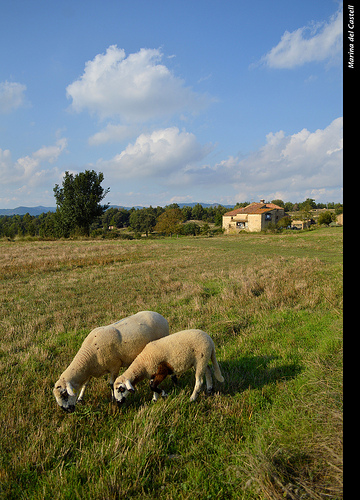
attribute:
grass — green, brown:
[1, 241, 342, 309]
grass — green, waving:
[227, 311, 335, 376]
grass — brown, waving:
[1, 244, 102, 269]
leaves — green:
[62, 179, 100, 223]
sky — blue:
[1, 0, 272, 45]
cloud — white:
[66, 44, 217, 128]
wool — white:
[90, 310, 169, 337]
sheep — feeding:
[48, 310, 225, 415]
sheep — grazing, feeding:
[53, 314, 108, 414]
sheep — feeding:
[111, 328, 226, 406]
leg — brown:
[150, 362, 174, 398]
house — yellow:
[221, 201, 287, 235]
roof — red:
[223, 203, 283, 214]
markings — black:
[117, 386, 128, 395]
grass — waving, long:
[227, 340, 342, 498]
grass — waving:
[173, 255, 343, 315]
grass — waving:
[2, 244, 151, 273]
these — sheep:
[51, 309, 226, 414]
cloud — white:
[255, 10, 342, 70]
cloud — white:
[108, 127, 213, 179]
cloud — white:
[210, 117, 342, 195]